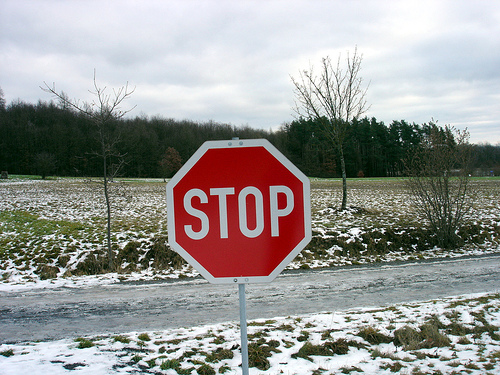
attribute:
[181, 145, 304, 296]
sign — red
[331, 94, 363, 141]
tree — bare, far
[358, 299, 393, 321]
snow — white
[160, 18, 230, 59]
sky — cloudy, gray, white